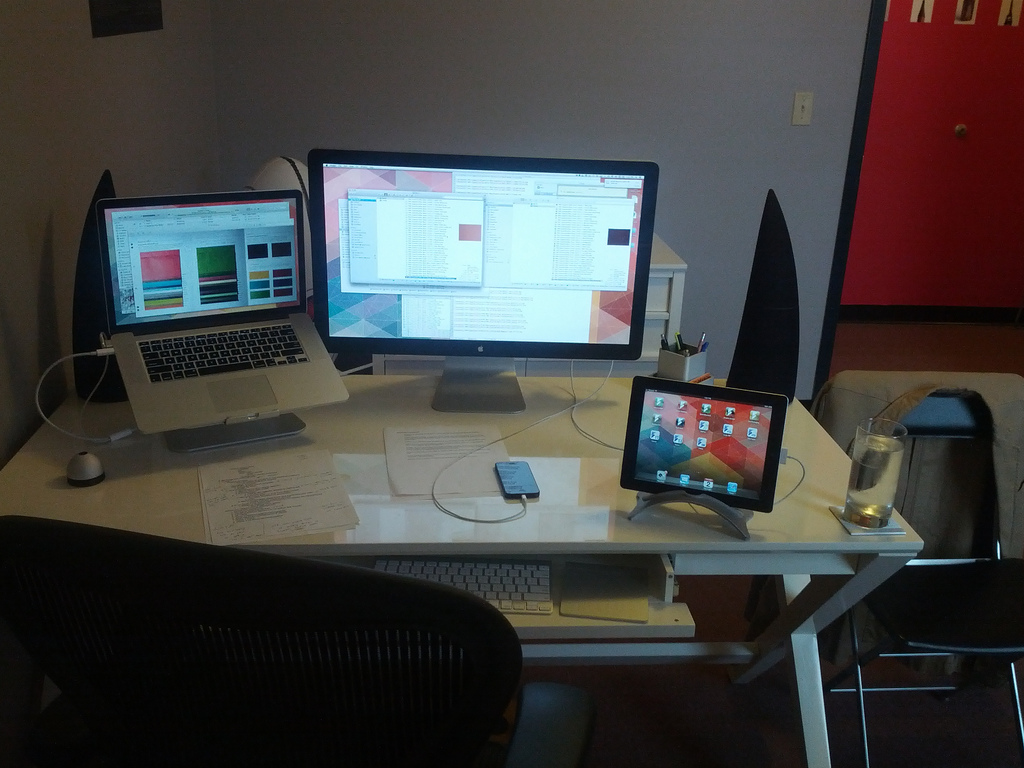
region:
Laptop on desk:
[92, 183, 346, 447]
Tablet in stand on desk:
[621, 373, 787, 529]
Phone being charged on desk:
[490, 455, 545, 517]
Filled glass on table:
[841, 395, 906, 539]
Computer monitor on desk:
[299, 140, 666, 407]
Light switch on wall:
[784, 85, 820, 131]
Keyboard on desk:
[367, 547, 554, 618]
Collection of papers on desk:
[185, 436, 514, 557]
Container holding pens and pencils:
[650, 323, 717, 393]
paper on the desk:
[199, 459, 333, 537]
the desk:
[129, 476, 196, 540]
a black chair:
[107, 585, 329, 706]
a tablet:
[635, 390, 766, 505]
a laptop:
[108, 215, 340, 416]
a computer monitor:
[314, 149, 660, 377]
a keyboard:
[456, 563, 540, 598]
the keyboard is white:
[462, 561, 548, 606]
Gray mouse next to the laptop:
[61, 442, 103, 488]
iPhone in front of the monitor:
[490, 454, 545, 497]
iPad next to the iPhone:
[617, 371, 788, 509]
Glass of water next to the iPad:
[842, 416, 910, 531]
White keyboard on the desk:
[370, 554, 551, 613]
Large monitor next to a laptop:
[310, 148, 658, 418]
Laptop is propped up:
[90, 192, 363, 442]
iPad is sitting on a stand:
[618, 366, 790, 522]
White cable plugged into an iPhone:
[430, 360, 617, 520]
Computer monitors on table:
[9, 35, 993, 748]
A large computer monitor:
[307, 135, 661, 361]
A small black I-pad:
[622, 370, 800, 522]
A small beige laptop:
[92, 170, 345, 453]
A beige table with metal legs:
[59, 379, 938, 730]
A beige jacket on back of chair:
[784, 336, 1020, 482]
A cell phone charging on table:
[464, 436, 562, 517]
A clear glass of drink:
[843, 404, 919, 572]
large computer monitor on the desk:
[305, 146, 660, 413]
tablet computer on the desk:
[616, 370, 791, 514]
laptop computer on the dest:
[97, 184, 351, 438]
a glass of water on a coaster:
[841, 414, 909, 528]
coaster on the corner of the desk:
[827, 500, 908, 538]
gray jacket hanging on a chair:
[748, 367, 1023, 680]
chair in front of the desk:
[0, 512, 592, 766]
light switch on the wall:
[787, 88, 819, 123]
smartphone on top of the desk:
[495, 458, 541, 500]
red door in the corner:
[838, 0, 1022, 318]